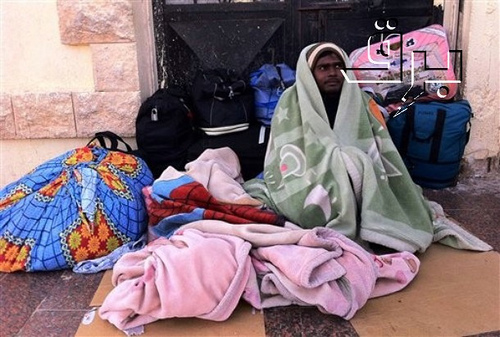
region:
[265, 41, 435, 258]
A man sitting outside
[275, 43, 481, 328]
A man sitting on cardboard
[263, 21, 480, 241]
A man in a green blanket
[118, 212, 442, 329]
A pink blanket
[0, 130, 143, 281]
A blue and red and yellow blanket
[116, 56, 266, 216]
Black bags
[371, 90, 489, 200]
A blue bag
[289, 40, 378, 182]
A dark skinned man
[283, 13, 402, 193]
A man with a mustache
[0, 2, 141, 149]
A brick and mortar wall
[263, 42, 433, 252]
a man wrapped in a green blanket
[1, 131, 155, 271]
a large blue and floral design bag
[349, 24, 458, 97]
a pink suitcase is behind the man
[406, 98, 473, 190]
a blue backpack is next to the man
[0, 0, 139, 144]
a brick building is behind the man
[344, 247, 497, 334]
the man is sitting on a flat piece of cardboard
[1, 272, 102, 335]
the man is on the tiled side walk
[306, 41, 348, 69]
the man is wearing a knit wool cap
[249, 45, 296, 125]
a blue backpack is hanging on a wall behind the man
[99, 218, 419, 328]
a pile of pink blankets in front of the man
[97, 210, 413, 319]
A wadded pink blanke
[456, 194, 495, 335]
A tile floor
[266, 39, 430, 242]
A man wrapped in a blanket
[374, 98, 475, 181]
A blue bag with black straps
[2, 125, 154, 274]
A large blue bag with red floral squares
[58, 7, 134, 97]
Stones at a doorframe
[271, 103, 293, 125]
A star on a blanket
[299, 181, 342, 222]
A moon on a blanket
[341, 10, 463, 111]
A pink suitcase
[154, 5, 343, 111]
A large black door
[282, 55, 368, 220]
One man is sitting in floor.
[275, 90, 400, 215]
Man is covering green blanket.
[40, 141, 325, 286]
Clothes are down in the floor.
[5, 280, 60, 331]
Floor is red color.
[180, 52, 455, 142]
Bags are arranged behind the man.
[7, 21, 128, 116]
Wall is pink color.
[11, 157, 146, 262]
One pile of clothes are tied together.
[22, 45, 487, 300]
Day time picture.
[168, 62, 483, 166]
Five bags are there.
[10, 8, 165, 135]
Stones are fixed to the wall.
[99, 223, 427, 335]
pink sheets on the floor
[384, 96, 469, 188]
blue bag on the right side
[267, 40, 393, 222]
a man sitting on the floor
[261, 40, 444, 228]
a green sheet involving the man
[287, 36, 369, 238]
afro-american guy in a green sheet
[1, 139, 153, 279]
blue tablecloth in the floor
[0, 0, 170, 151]
bricks on the wall in the left side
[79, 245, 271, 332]
a piece of cardboard under the pink sheet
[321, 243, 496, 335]
a piece of cardboard in the right side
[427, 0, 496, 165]
a beige wall in the right side